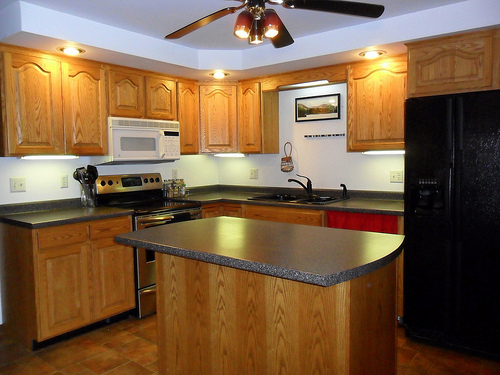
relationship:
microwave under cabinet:
[95, 116, 182, 166] [106, 62, 177, 119]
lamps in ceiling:
[58, 43, 85, 57] [1, 0, 498, 80]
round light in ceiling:
[210, 68, 226, 80] [1, 0, 498, 80]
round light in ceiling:
[359, 47, 378, 61] [1, 0, 498, 80]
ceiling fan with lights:
[166, 1, 384, 51] [232, 26, 280, 46]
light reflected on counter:
[224, 19, 292, 48] [130, 217, 410, 283]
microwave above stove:
[103, 112, 187, 166] [90, 166, 202, 325]